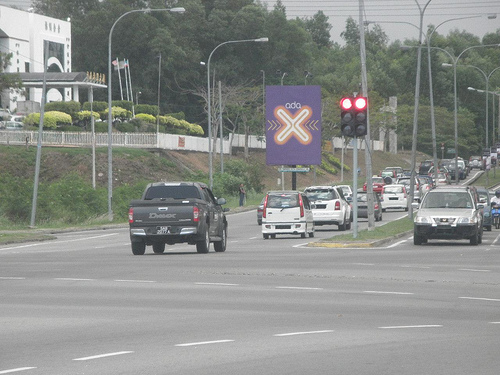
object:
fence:
[0, 128, 384, 156]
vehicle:
[379, 183, 409, 213]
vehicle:
[334, 184, 355, 202]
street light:
[340, 97, 354, 111]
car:
[412, 188, 482, 243]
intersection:
[0, 231, 499, 373]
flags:
[112, 57, 124, 101]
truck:
[125, 178, 230, 256]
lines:
[362, 289, 414, 296]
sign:
[265, 84, 322, 167]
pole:
[28, 39, 50, 230]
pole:
[106, 8, 172, 223]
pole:
[205, 38, 256, 194]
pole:
[357, 0, 376, 234]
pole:
[351, 136, 358, 240]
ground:
[1, 143, 499, 373]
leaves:
[169, 46, 175, 50]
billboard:
[264, 85, 322, 167]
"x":
[272, 104, 312, 143]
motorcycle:
[489, 204, 500, 230]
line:
[457, 294, 498, 302]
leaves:
[305, 50, 312, 56]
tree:
[213, 4, 272, 88]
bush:
[53, 125, 83, 141]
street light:
[107, 6, 187, 223]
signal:
[354, 97, 368, 110]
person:
[238, 182, 247, 208]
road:
[0, 154, 499, 375]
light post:
[374, 21, 440, 190]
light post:
[438, 59, 499, 172]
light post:
[407, 0, 435, 221]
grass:
[0, 141, 434, 245]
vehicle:
[261, 189, 315, 240]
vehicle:
[302, 184, 352, 231]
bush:
[17, 124, 47, 140]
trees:
[270, 20, 320, 87]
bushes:
[113, 121, 137, 133]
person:
[489, 187, 500, 210]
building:
[0, 4, 108, 113]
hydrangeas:
[43, 110, 74, 126]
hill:
[0, 141, 419, 224]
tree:
[119, 26, 213, 137]